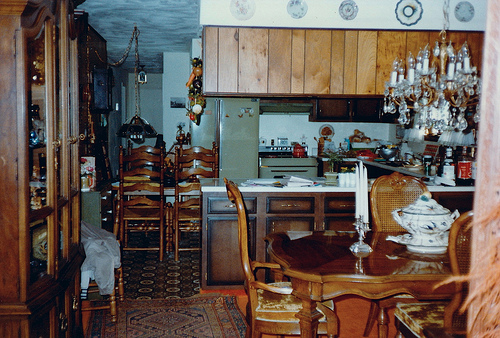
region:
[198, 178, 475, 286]
a white counter above dark brown drawers and cabinets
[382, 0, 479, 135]
crystal chandelier hanging from above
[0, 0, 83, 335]
tall wooden curio cabinet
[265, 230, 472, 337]
highly polished wooden table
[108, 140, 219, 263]
seats on both sides of a dining area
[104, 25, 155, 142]
lamp hung on a long chain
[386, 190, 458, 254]
covered ceramic soup tureen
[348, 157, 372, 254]
three white candles in a candelabra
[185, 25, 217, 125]
artificial fruit hung from the side of a cabinet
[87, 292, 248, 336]
part of a narrow woven rug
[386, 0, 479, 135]
Chandelier hanging over table.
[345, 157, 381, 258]
Silver candle holder with white candles.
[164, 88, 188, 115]
Picture with no frame hanging on the wall.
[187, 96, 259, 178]
Green refrigerator in kitchen.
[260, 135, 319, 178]
Green stove beside refrigerator in kitchen.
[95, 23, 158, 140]
Hanging lamp and chain over table.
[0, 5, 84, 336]
Wood and glass china cabinet against wall.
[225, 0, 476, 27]
Five mismatched dishes hanging on kitchen wall.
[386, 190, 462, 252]
Blue and serving dish and platter on table.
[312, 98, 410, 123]
Three dark brown kitchen cabinets hanging above counter.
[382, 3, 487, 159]
A chandelier hanging over a table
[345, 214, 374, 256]
A candlestick holder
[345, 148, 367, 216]
Long white candlesticks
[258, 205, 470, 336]
A wooden dining room table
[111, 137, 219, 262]
Wooden chairs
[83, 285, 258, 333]
An area rug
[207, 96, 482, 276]
Wooden cabinetry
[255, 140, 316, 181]
A creamed color stove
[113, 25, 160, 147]
A light hanging over a table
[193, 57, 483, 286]
A kitchen area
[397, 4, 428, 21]
PLATES ON THE WALL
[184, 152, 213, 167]
CHAIRS MADE OUT OF WOOD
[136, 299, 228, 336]
RUG ON THE FLOOR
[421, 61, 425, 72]
CANDLE LIGHT HANGING FROM LAMP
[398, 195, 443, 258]
TEA POT ON THE TABLE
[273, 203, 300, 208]
GOLD HANDLE ON THE DRAWERS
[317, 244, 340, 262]
TABLE MADE OUT OF WOOD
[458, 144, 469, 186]
BEER BOTTLE ON THE TABLE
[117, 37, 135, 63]
CHAIN HANGING FROM THE CEILING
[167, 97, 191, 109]
PICTURE ON THE WALL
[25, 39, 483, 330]
a view of the kitchen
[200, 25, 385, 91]
is made of wood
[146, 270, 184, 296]
pattern on the floor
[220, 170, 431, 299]
chairs at the table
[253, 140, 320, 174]
the oven is green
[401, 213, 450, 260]
large teapot on table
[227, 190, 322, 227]
the cabinets are wooden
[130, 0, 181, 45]
the wall is blue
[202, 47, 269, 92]
light reflection on cabinet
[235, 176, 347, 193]
the counter is white